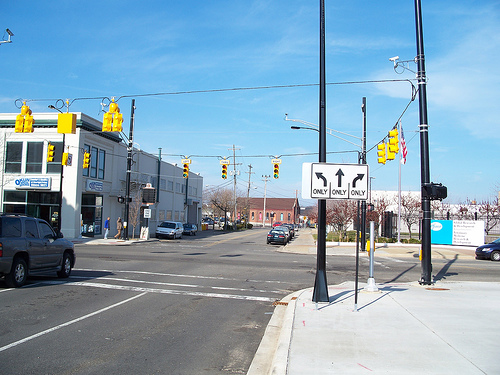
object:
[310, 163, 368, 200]
sign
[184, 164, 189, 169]
light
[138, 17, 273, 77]
sky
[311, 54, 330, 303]
pole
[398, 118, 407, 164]
flag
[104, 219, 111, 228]
shirt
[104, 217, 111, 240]
man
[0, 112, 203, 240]
building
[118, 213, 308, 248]
street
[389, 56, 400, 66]
camera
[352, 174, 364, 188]
arrow